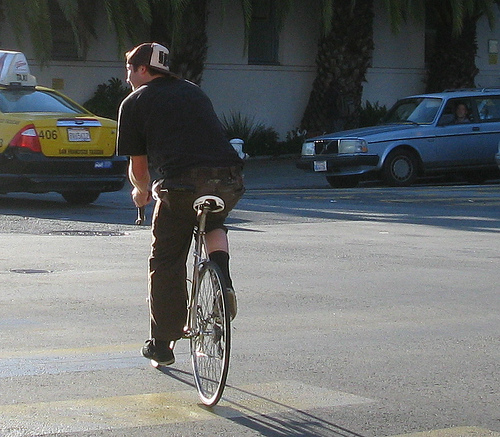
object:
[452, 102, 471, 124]
man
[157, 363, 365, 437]
shadow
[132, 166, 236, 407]
bicycle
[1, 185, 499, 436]
pavement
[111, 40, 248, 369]
guy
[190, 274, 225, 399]
wheel spokes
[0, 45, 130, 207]
taxi cab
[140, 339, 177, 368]
shoe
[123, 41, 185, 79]
baseball cap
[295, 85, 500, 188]
car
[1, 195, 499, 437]
intersection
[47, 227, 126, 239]
manhole cover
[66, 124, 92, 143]
license plate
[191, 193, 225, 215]
seat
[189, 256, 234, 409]
back tire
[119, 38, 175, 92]
person's head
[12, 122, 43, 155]
tail light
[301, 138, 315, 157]
headlights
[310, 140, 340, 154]
gril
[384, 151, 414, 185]
tire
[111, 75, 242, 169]
shirt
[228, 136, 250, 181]
fire hydrant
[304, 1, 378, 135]
tree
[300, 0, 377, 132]
trunk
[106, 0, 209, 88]
tree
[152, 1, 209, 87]
trunk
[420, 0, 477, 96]
tree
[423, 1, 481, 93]
trunk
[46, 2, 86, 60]
window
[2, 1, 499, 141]
building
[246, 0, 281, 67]
window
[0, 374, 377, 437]
line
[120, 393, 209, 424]
smudge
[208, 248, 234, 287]
sock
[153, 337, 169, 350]
sock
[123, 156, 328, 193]
side walk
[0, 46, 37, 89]
sign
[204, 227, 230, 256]
bare leg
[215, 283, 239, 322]
tennis shoe